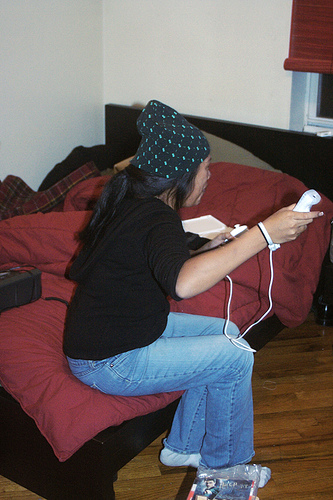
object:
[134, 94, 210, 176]
hat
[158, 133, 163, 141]
dots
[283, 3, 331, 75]
blinds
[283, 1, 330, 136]
window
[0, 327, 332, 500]
floors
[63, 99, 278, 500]
woman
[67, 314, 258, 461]
jeans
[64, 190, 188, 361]
shirt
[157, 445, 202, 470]
socks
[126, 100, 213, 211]
head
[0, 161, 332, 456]
blanket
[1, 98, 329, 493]
bed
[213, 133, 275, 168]
pillow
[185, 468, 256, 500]
book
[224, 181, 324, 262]
wiimote